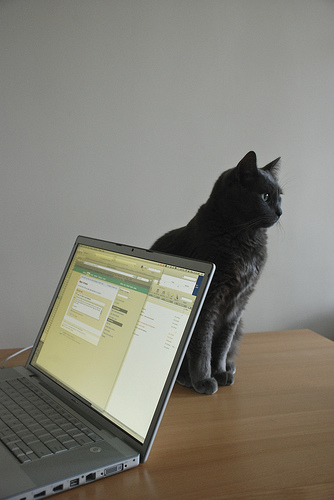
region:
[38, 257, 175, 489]
the laptop is open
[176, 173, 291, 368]
cat is on th table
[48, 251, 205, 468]
laptop is on the table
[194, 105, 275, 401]
cat is grey in color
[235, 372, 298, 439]
table is brown in color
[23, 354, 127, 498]
laptop is grey in color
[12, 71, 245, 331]
the wall is behind the table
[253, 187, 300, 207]
the cat eyes are white and black in coor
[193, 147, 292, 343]
cat is looking in one direction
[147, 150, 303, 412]
this is a cat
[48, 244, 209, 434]
this is a computer screen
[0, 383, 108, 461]
this is a computer keyboard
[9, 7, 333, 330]
this is a wall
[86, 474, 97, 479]
his is a port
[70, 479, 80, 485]
his is a port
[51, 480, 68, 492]
his is a port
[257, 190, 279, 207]
his is a cat's eye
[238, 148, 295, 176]
these are a cat's ears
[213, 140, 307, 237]
head of a cat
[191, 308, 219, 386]
leg of a cat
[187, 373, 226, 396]
paw of a cat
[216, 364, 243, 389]
paw of a cat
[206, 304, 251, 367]
leg of a cat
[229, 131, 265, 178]
ear of a cat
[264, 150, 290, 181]
ear of a cat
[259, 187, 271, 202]
eye of a cat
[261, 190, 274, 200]
an eye of a cat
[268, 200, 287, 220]
nose of a cat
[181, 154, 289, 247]
this is a cat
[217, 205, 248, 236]
the cat is black in color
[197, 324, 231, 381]
these are the legs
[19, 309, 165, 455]
this is a laptop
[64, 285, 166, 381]
the laptop is on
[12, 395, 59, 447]
these are the buttons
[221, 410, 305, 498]
this is the table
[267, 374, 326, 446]
the table is wooden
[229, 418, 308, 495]
the table is brown in collor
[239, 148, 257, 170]
this is the ear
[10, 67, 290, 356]
this is in an office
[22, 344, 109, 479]
the laptop is gray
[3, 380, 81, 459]
this is a keyboard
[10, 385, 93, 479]
the keyboard is gray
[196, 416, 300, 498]
the tabletop is wooden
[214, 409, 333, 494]
this is woodgrain patterned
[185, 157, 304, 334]
the cat is dark gray